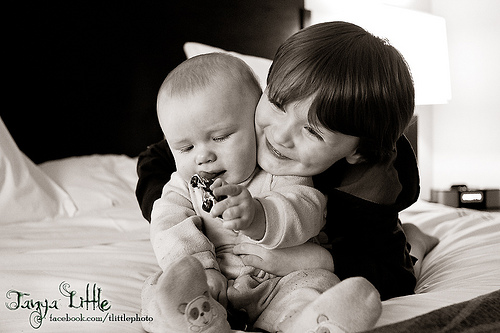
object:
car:
[189, 171, 227, 212]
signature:
[4, 282, 111, 329]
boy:
[149, 51, 383, 333]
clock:
[431, 184, 500, 210]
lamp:
[307, 2, 453, 105]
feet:
[145, 253, 229, 332]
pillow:
[179, 39, 274, 90]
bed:
[0, 112, 499, 333]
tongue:
[197, 171, 216, 180]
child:
[138, 19, 441, 300]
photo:
[4, 2, 499, 332]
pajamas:
[144, 171, 382, 331]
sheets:
[0, 154, 496, 328]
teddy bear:
[177, 289, 218, 332]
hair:
[265, 18, 417, 162]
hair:
[152, 51, 263, 101]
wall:
[305, 1, 497, 206]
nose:
[194, 148, 217, 165]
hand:
[208, 177, 254, 231]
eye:
[212, 132, 235, 142]